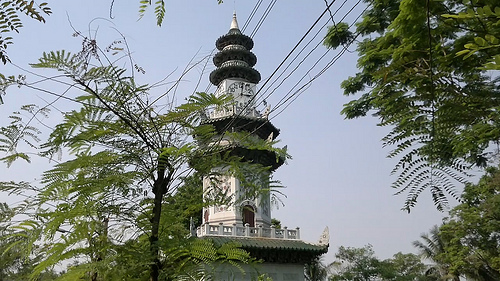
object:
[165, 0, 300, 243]
temple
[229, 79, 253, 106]
clock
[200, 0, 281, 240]
tower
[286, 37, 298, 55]
lines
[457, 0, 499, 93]
trees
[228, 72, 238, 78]
rings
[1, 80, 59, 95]
left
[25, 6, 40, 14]
leaves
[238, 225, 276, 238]
railing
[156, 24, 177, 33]
sky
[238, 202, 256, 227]
door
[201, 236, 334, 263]
roof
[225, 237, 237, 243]
shingles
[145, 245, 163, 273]
trunk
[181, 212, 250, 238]
balcony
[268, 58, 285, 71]
wires